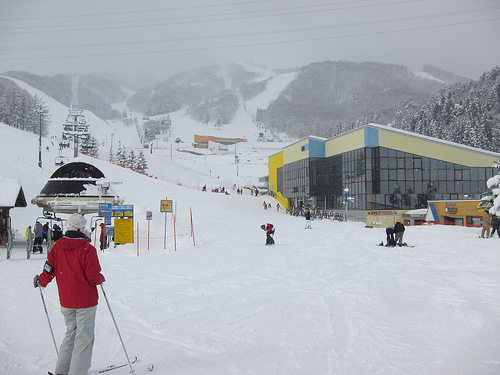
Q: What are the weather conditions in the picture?
A: It is cloudy.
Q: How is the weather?
A: It is cloudy.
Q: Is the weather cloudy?
A: Yes, it is cloudy.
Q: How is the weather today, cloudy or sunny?
A: It is cloudy.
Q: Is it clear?
A: No, it is cloudy.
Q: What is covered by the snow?
A: The ground is covered by the snow.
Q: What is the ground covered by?
A: The ground is covered by the snow.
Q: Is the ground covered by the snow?
A: Yes, the ground is covered by the snow.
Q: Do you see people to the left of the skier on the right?
A: Yes, there is a person to the left of the skier.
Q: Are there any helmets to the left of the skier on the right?
A: No, there is a person to the left of the skier.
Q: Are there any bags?
A: No, there are no bags.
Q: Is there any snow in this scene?
A: Yes, there is snow.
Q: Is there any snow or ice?
A: Yes, there is snow.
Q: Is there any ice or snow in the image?
A: Yes, there is snow.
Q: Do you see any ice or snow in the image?
A: Yes, there is snow.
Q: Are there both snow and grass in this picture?
A: No, there is snow but no grass.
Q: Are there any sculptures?
A: No, there are no sculptures.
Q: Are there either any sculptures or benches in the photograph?
A: No, there are no sculptures or benches.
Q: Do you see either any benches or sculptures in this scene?
A: No, there are no sculptures or benches.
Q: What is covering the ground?
A: The snow is covering the ground.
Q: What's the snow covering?
A: The snow is covering the ground.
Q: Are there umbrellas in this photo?
A: No, there are no umbrellas.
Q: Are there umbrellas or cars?
A: No, there are no umbrellas or cars.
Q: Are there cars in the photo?
A: No, there are no cars.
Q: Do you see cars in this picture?
A: No, there are no cars.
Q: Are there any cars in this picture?
A: No, there are no cars.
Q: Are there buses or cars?
A: No, there are no cars or buses.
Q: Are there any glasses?
A: No, there are no glasses.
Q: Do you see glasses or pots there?
A: No, there are no glasses or pots.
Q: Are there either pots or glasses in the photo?
A: No, there are no glasses or pots.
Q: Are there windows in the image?
A: Yes, there is a window.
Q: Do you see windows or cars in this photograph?
A: Yes, there is a window.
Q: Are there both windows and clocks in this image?
A: No, there is a window but no clocks.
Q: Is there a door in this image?
A: No, there are no doors.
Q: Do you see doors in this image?
A: No, there are no doors.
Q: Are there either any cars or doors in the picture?
A: No, there are no doors or cars.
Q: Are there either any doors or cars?
A: No, there are no doors or cars.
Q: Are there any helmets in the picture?
A: No, there are no helmets.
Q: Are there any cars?
A: No, there are no cars.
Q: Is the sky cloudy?
A: Yes, the sky is cloudy.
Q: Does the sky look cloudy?
A: Yes, the sky is cloudy.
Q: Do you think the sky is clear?
A: No, the sky is cloudy.